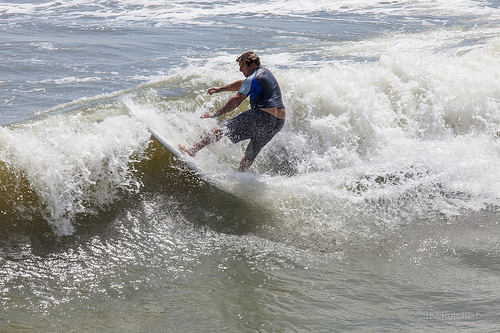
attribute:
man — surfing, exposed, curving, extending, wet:
[185, 41, 296, 180]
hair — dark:
[231, 49, 262, 65]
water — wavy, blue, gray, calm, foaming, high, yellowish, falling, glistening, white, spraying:
[0, 2, 498, 331]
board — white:
[114, 99, 284, 204]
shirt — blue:
[233, 71, 295, 109]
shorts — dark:
[212, 104, 286, 165]